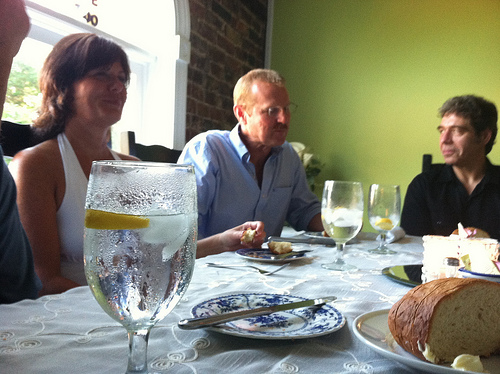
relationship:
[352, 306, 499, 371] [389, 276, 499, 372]
plate with bread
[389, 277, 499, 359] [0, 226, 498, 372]
bread on table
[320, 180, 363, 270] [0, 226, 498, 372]
drink on table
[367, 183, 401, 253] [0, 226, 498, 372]
drink on table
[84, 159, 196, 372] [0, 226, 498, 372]
drink on table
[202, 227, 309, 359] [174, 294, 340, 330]
plate has butter knife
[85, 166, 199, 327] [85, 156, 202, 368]
condensation on glass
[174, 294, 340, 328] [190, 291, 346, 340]
butter knife lying on plate